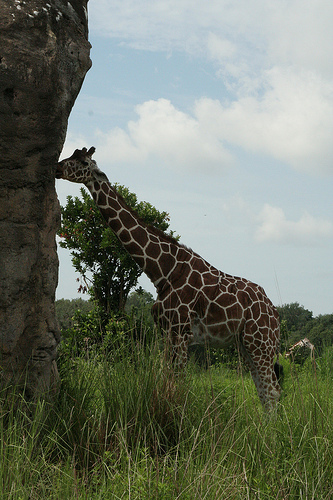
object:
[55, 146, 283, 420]
giraffe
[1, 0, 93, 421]
wall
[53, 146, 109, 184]
head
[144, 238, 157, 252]
spot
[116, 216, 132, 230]
spot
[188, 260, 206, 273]
spot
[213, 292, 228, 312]
spot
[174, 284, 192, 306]
spot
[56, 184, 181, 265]
leaves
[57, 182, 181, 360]
tree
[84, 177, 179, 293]
neck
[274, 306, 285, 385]
tail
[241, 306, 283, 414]
hind leg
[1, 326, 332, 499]
grass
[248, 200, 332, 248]
cloud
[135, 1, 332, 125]
sky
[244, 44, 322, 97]
cloud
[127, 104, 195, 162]
cloud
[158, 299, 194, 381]
leg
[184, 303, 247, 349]
belly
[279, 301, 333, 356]
trees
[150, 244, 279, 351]
body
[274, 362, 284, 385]
hair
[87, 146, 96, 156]
horn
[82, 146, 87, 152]
horn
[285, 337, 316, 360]
wood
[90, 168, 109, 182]
ear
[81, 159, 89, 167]
eye